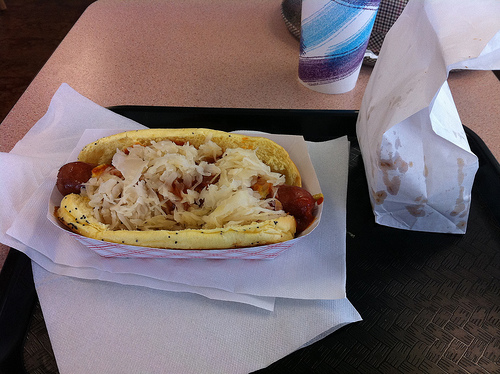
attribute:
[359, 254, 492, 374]
table —  woven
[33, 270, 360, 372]
napkins —  white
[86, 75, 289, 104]
table — brown and speckled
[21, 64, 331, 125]
table — tan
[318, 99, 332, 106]
cup —  white, blue and purple 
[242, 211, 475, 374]
tray — black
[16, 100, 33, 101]
floor — brown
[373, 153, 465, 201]
bag — greasy and white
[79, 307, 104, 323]
tissue —  white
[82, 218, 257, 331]
tissue —  white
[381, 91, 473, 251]
bag —  white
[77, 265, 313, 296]
napkin —  white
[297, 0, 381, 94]
cup — blue, purple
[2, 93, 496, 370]
tray — black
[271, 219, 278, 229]
seed — black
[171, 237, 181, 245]
seed — black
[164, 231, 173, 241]
seed — black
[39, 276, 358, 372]
tissue — white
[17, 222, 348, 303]
tissue — white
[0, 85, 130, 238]
tissue — white